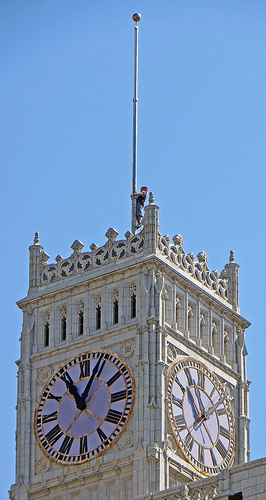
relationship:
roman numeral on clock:
[39, 408, 59, 425] [31, 346, 140, 471]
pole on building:
[129, 16, 141, 193] [87, 244, 205, 358]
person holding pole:
[130, 185, 148, 225] [129, 23, 139, 237]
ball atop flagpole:
[130, 11, 144, 21] [130, 26, 137, 169]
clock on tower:
[32, 349, 135, 468] [32, 275, 180, 422]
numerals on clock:
[173, 371, 194, 385] [53, 361, 125, 405]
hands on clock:
[184, 372, 225, 423] [165, 358, 225, 425]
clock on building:
[32, 349, 135, 468] [102, 287, 194, 338]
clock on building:
[32, 349, 135, 468] [71, 295, 189, 347]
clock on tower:
[32, 349, 135, 468] [90, 281, 178, 311]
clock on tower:
[32, 349, 135, 468] [68, 297, 166, 327]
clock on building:
[32, 349, 135, 468] [81, 295, 180, 340]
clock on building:
[32, 349, 135, 468] [82, 311, 173, 323]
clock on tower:
[9, 353, 127, 405] [42, 292, 135, 333]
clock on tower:
[32, 349, 135, 468] [53, 297, 145, 327]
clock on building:
[32, 349, 135, 468] [111, 294, 210, 323]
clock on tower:
[32, 349, 135, 468] [73, 282, 170, 315]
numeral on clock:
[58, 352, 107, 378] [41, 359, 140, 410]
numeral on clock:
[98, 352, 119, 372] [39, 377, 122, 413]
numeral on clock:
[103, 367, 124, 383] [32, 355, 133, 418]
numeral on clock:
[107, 381, 160, 409] [39, 351, 156, 457]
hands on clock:
[60, 351, 108, 409] [32, 349, 135, 468]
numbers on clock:
[170, 367, 232, 466] [165, 356, 235, 477]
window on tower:
[130, 292, 137, 320] [12, 13, 264, 498]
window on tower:
[176, 302, 180, 325] [12, 13, 264, 498]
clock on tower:
[32, 349, 135, 468] [12, 13, 264, 498]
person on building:
[127, 186, 147, 228] [7, 12, 265, 500]